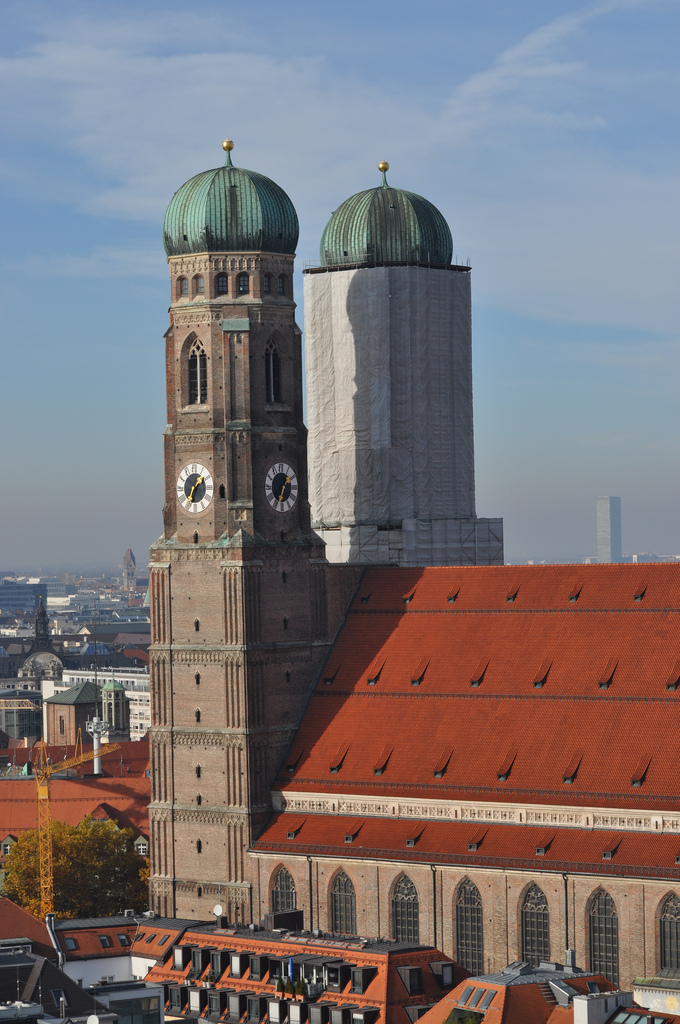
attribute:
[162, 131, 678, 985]
building — tall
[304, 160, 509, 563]
building — tall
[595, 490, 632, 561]
building — tall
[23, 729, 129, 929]
crane — large, yellow